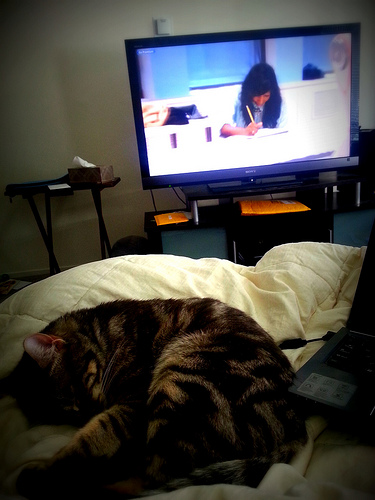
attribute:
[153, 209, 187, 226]
package — orange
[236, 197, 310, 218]
package — orange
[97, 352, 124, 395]
whisker — white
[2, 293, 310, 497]
cat — striped, black, yellow, brown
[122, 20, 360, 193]
television — large, black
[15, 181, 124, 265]
tray table — black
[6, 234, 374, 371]
blanket — yellow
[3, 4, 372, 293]
wall — white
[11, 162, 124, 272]
table — small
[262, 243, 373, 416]
laptop — black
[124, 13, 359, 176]
television — large, black framed